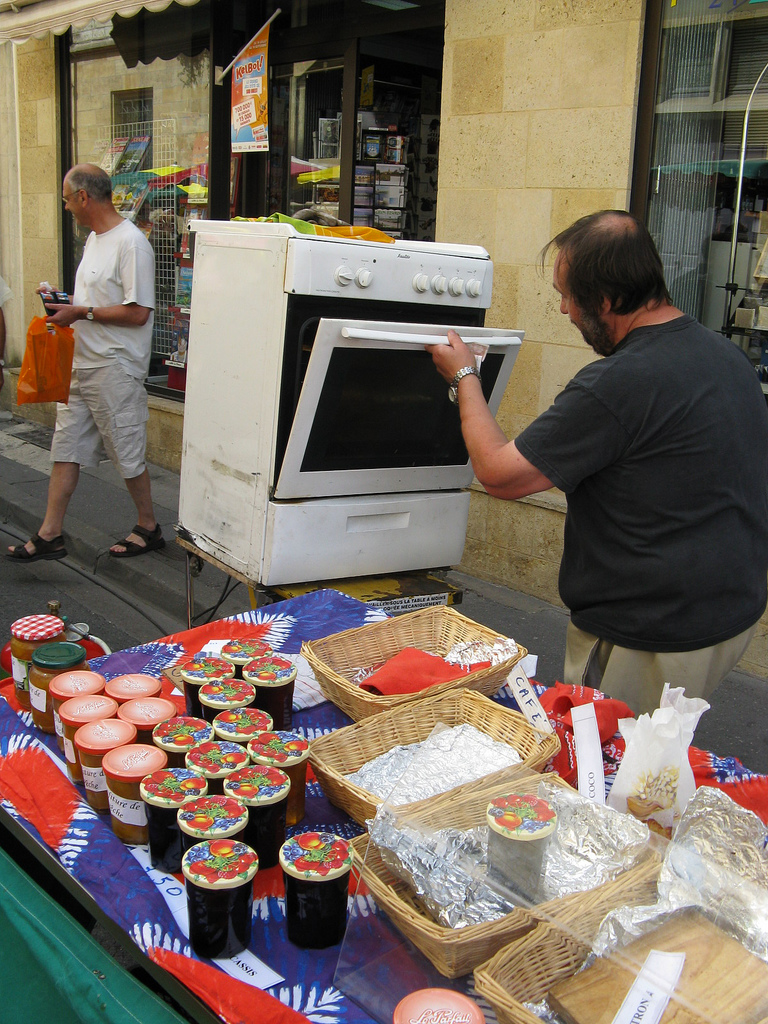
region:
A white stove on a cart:
[179, 215, 532, 584]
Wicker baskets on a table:
[303, 604, 710, 972]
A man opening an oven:
[423, 209, 766, 708]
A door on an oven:
[271, 306, 524, 493]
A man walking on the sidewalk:
[2, 160, 165, 565]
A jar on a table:
[175, 837, 262, 955]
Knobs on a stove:
[333, 258, 487, 304]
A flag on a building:
[211, 10, 279, 155]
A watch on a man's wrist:
[449, 358, 480, 382]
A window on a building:
[638, 0, 760, 392]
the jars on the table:
[5, 607, 348, 950]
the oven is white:
[181, 204, 500, 583]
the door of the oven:
[283, 308, 527, 504]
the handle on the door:
[327, 320, 523, 358]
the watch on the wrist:
[437, 363, 480, 410]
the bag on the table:
[599, 674, 716, 837]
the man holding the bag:
[13, 151, 173, 560]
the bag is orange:
[14, 309, 73, 409]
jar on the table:
[177, 886, 248, 956]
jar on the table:
[283, 855, 349, 954]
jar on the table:
[479, 798, 536, 895]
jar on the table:
[102, 778, 144, 844]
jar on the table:
[86, 755, 109, 807]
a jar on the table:
[285, 826, 383, 955]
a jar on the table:
[171, 868, 291, 960]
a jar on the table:
[184, 791, 216, 828]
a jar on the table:
[234, 780, 282, 832]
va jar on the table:
[256, 716, 330, 827]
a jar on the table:
[78, 732, 132, 815]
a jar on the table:
[48, 710, 122, 791]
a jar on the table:
[2, 624, 45, 713]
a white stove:
[187, 219, 521, 589]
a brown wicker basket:
[303, 601, 524, 722]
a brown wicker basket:
[311, 686, 560, 828]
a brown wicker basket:
[337, 769, 651, 977]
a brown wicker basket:
[477, 861, 763, 1022]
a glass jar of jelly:
[182, 841, 255, 957]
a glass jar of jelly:
[276, 832, 353, 949]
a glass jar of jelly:
[179, 796, 247, 844]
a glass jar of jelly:
[139, 768, 209, 872]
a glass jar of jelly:
[222, 761, 288, 860]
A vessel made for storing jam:
[279, 829, 351, 946]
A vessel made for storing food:
[183, 836, 259, 957]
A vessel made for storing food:
[179, 793, 250, 842]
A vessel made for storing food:
[101, 741, 169, 843]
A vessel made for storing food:
[75, 717, 137, 805]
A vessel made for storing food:
[26, 641, 87, 733]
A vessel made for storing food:
[8, 612, 65, 709]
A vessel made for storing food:
[182, 654, 235, 719]